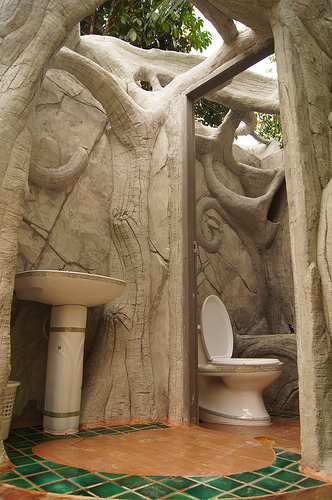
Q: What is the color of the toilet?
A: White.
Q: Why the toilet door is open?
A: No one is using it.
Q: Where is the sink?
A: Outside the toilet.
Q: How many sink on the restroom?
A: One.